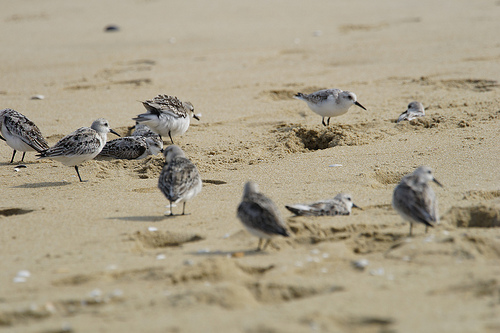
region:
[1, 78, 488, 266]
a group of birds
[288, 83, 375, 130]
gray and white bird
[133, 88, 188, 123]
feathers are ruffled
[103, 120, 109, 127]
black eye on the side of the face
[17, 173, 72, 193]
shadow on the ground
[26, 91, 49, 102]
rock on the sand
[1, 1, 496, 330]
ground covered in sand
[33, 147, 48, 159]
feathers on the tail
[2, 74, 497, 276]
birds on the sand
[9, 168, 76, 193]
shadow from a bird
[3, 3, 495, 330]
a pack of birds on the beach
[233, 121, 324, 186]
a sandy brown beach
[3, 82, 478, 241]
a flock of grey and white birds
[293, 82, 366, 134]
a white gray and black bird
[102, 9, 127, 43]
a small rock in the distance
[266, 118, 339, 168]
a large whole dug in teh sand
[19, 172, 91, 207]
the shadow of a bird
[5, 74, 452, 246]
Ten grey and white birds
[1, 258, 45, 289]
a small seashell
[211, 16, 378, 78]
sun shining off of the sand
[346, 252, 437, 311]
part f a sand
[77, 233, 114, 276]
part of a ground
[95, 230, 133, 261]
part of a ground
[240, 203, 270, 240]
edge of a wing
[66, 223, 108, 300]
part of a ground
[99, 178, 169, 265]
part of of a snd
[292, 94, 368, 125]
the bird is on the ground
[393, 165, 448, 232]
the bird is on the ground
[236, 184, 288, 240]
the bird is on the ground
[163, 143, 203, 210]
the bird is on the ground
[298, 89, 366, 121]
the bird is hwite and brown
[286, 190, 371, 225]
te bird is lying on the ground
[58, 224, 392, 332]
the sand is brown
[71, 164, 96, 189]
the bird is standing on one leg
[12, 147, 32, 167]
the bord is standin gon two legs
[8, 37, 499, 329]
the bids are busking on the sun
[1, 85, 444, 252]
Birds in the sand.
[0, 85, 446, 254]
Birds on a beach.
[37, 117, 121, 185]
A bird in the sand.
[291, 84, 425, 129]
Two birds in the sand.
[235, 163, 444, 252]
Three birds in the sand.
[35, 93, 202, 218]
Four birds in the sand.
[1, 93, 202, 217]
Five birds in the sand.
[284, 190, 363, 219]
A bird laying down.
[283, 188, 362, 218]
A bird laying in the sand.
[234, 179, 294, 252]
A blurry bird in the sand.